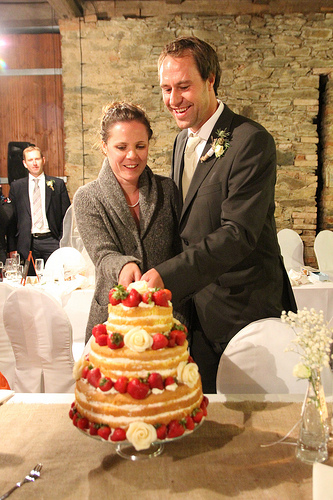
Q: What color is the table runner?
A: Tan.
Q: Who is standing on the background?
A: A man.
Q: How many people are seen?
A: Three.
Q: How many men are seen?
A: Two.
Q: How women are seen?
A: One.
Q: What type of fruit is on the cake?
A: Strawberry.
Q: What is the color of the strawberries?
A: Red.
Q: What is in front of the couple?
A: Cake.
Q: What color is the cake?
A: Brown and red.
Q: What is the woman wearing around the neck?
A: Necklace.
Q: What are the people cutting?
A: A cake.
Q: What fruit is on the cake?
A: Strawberries.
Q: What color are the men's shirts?
A: White.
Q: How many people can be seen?
A: Three.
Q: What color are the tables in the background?
A: White.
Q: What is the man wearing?
A: A suit.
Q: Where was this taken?
A: At a wedding.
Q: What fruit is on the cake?
A: Strawberries.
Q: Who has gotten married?
A: The man and woman.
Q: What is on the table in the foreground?
A: A cake.